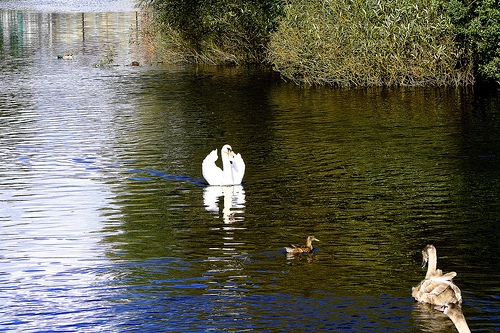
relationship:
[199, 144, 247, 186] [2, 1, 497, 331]
birds in river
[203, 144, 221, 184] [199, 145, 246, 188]
wing on swan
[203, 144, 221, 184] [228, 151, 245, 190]
wing on wing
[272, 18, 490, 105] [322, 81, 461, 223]
trees on river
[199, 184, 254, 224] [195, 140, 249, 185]
reflection of swan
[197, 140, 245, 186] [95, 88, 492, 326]
birds are in water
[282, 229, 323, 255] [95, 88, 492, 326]
birds are in water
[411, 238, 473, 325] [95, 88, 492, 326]
birds are in water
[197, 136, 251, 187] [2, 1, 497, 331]
swan in river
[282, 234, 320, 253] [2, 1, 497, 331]
birds in river